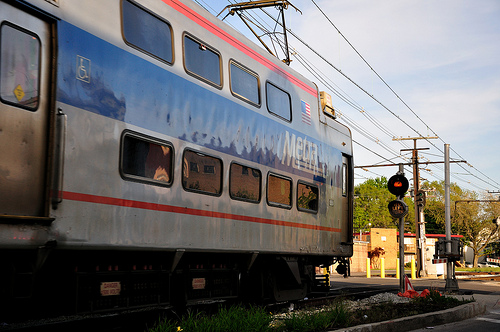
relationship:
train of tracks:
[0, 0, 359, 257] [260, 284, 400, 317]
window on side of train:
[118, 127, 178, 188] [0, 0, 357, 292]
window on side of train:
[182, 142, 224, 195] [0, 0, 357, 292]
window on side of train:
[228, 158, 263, 203] [0, 0, 357, 292]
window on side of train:
[266, 166, 295, 208] [0, 0, 357, 292]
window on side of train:
[295, 175, 323, 215] [0, 0, 357, 292]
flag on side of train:
[299, 99, 318, 126] [0, 0, 357, 292]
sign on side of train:
[73, 51, 93, 84] [0, 0, 357, 292]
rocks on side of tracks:
[274, 292, 431, 321] [309, 285, 498, 298]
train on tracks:
[0, 0, 357, 292] [257, 282, 393, 314]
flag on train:
[292, 96, 312, 124] [0, 0, 357, 292]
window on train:
[116, 125, 177, 190] [0, 0, 357, 292]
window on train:
[225, 156, 265, 206] [0, 0, 357, 292]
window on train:
[265, 167, 294, 209] [0, 0, 357, 292]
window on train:
[295, 177, 320, 215] [0, 0, 357, 292]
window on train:
[115, 0, 177, 67] [0, 0, 357, 292]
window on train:
[181, 27, 226, 90] [0, 0, 357, 292]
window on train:
[227, 56, 262, 110] [0, 0, 357, 292]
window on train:
[264, 77, 294, 122] [0, 0, 357, 292]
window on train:
[340, 162, 347, 197] [0, 0, 357, 292]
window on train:
[0, 16, 42, 113] [0, 0, 357, 292]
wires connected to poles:
[192, 0, 499, 205] [390, 125, 437, 246]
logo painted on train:
[271, 130, 331, 187] [0, 0, 357, 292]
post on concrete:
[365, 248, 372, 283] [393, 253, 499, 323]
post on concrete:
[379, 253, 386, 281] [393, 253, 499, 323]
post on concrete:
[393, 253, 402, 285] [393, 253, 499, 323]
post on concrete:
[411, 253, 418, 283] [393, 253, 499, 323]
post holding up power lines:
[390, 130, 435, 281] [206, 1, 498, 191]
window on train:
[177, 143, 224, 204] [0, 0, 357, 292]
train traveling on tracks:
[0, 0, 357, 292] [257, 280, 379, 309]